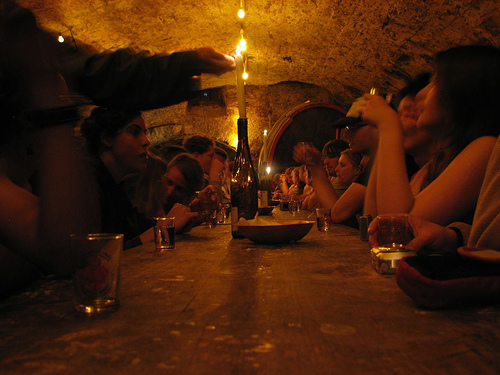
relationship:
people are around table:
[66, 107, 231, 210] [242, 272, 329, 305]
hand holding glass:
[163, 202, 209, 229] [156, 227, 177, 256]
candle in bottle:
[227, 51, 257, 124] [225, 165, 257, 212]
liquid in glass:
[260, 217, 291, 230] [156, 227, 177, 256]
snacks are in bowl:
[238, 205, 305, 226] [246, 224, 303, 246]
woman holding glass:
[396, 52, 474, 221] [156, 227, 177, 256]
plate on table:
[364, 257, 401, 274] [242, 272, 329, 305]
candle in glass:
[227, 51, 257, 124] [156, 227, 177, 256]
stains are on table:
[139, 263, 190, 297] [242, 272, 329, 305]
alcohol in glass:
[188, 73, 218, 113] [156, 227, 177, 256]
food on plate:
[179, 196, 212, 228] [364, 257, 401, 274]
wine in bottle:
[227, 144, 251, 167] [225, 165, 257, 212]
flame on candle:
[220, 32, 244, 51] [227, 51, 257, 124]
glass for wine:
[156, 227, 177, 256] [227, 144, 251, 167]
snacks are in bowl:
[258, 217, 284, 239] [246, 224, 303, 246]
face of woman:
[409, 75, 444, 132] [396, 52, 474, 221]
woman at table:
[396, 52, 474, 221] [242, 272, 329, 305]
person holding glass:
[184, 133, 224, 184] [156, 227, 177, 256]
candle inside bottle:
[227, 51, 257, 124] [225, 165, 257, 212]